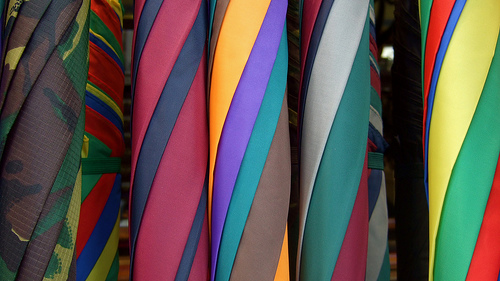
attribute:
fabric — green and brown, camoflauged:
[12, 7, 99, 249]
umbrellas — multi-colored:
[3, 2, 498, 279]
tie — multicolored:
[295, 0, 390, 279]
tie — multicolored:
[0, 0, 88, 280]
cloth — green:
[84, 140, 128, 186]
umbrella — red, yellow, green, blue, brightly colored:
[416, 0, 499, 280]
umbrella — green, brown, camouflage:
[0, 1, 89, 278]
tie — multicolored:
[414, 1, 496, 279]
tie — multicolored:
[293, 1, 400, 279]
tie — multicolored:
[204, 2, 297, 279]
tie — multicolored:
[129, 4, 217, 279]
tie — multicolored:
[72, 2, 127, 279]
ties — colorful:
[34, 23, 476, 265]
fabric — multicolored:
[3, 5, 495, 275]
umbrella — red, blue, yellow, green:
[70, 5, 130, 274]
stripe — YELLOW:
[412, 3, 494, 273]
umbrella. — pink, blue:
[107, 8, 228, 279]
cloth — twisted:
[61, 24, 144, 279]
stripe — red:
[479, 205, 499, 270]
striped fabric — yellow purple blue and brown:
[208, 2, 292, 279]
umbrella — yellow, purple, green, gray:
[198, 3, 293, 279]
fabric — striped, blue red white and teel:
[249, 57, 388, 222]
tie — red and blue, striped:
[75, 0, 137, 279]